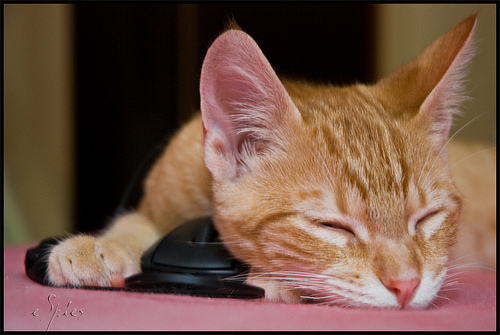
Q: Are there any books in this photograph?
A: No, there are no books.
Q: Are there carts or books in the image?
A: No, there are no books or carts.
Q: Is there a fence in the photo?
A: No, there are no fences.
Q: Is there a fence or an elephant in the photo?
A: No, there are no fences or elephants.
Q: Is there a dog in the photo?
A: No, there are no dogs.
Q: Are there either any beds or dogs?
A: No, there are no dogs or beds.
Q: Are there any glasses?
A: No, there are no glasses.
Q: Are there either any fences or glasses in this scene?
A: No, there are no glasses or fences.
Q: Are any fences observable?
A: No, there are no fences.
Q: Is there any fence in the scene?
A: No, there are no fences.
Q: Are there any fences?
A: No, there are no fences.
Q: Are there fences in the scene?
A: No, there are no fences.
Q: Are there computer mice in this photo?
A: Yes, there is a computer mouse.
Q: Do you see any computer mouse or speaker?
A: Yes, there is a computer mouse.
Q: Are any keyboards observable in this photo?
A: No, there are no keyboards.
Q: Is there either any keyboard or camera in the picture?
A: No, there are no keyboards or cameras.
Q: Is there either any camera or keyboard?
A: No, there are no keyboards or cameras.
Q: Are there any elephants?
A: No, there are no elephants.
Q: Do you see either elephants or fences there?
A: No, there are no elephants or fences.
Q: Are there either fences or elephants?
A: No, there are no elephants or fences.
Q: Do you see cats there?
A: Yes, there is a cat.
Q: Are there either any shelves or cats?
A: Yes, there is a cat.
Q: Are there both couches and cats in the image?
A: No, there is a cat but no couches.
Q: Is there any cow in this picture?
A: No, there are no cows.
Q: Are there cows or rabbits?
A: No, there are no cows or rabbits.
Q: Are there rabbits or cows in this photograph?
A: No, there are no cows or rabbits.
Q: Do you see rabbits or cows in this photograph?
A: No, there are no cows or rabbits.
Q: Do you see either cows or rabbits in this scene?
A: No, there are no cows or rabbits.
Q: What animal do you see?
A: The animal is a cat.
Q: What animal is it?
A: The animal is a cat.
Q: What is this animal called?
A: This is a cat.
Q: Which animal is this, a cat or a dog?
A: This is a cat.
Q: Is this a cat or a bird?
A: This is a cat.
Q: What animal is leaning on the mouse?
A: The cat is leaning on the mouse.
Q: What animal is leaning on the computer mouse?
A: The cat is leaning on the mouse.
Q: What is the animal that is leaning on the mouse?
A: The animal is a cat.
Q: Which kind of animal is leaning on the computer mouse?
A: The animal is a cat.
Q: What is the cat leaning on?
A: The cat is leaning on the computer mouse.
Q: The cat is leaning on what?
A: The cat is leaning on the computer mouse.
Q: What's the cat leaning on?
A: The cat is leaning on the computer mouse.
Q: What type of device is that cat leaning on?
A: The cat is leaning on the computer mouse.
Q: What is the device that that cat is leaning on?
A: The device is a computer mouse.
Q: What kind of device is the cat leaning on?
A: The cat is leaning on the computer mouse.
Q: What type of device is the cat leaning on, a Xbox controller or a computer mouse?
A: The cat is leaning on a computer mouse.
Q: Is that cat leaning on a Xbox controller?
A: No, the cat is leaning on the computer mouse.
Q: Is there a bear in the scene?
A: No, there are no bears.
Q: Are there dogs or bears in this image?
A: No, there are no bears or dogs.